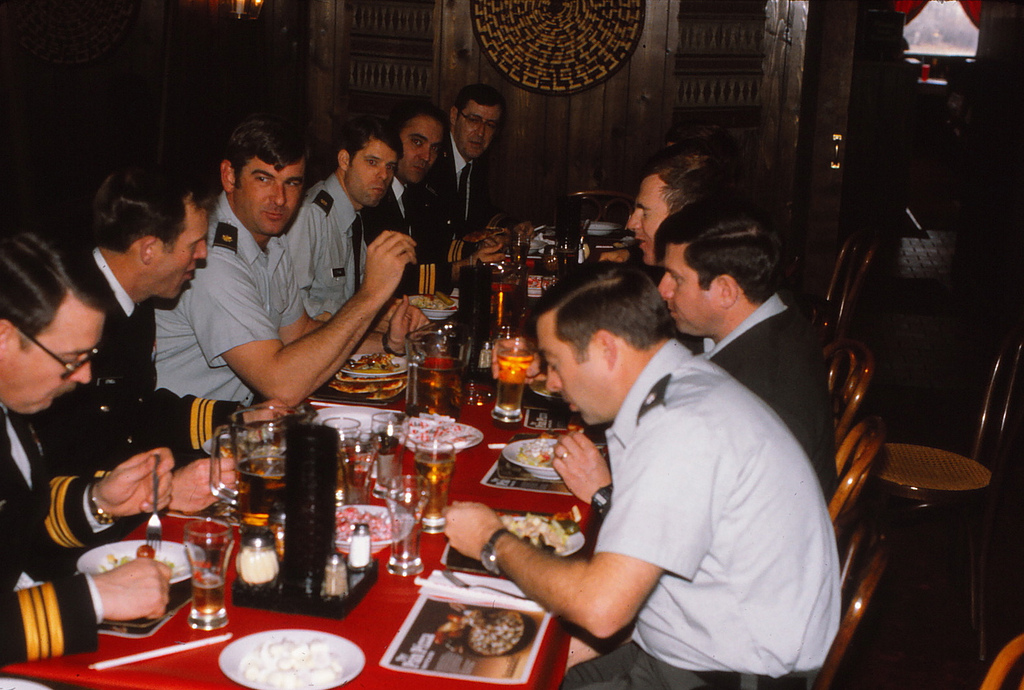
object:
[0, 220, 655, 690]
plate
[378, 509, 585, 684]
placemat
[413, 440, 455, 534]
glass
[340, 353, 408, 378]
bowl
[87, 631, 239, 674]
straw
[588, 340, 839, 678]
shirt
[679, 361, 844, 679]
rounded back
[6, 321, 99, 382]
glasses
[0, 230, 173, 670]
man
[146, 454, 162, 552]
fork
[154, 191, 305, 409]
white uniform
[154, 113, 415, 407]
man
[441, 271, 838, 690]
eating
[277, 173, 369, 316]
white uniform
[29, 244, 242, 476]
blue uniform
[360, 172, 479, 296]
blue uniform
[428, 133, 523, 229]
blue uniform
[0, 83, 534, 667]
military men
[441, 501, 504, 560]
left hand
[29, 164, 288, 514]
man